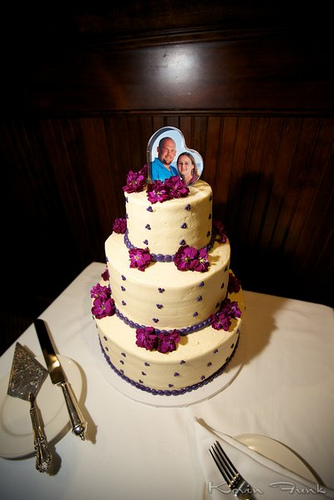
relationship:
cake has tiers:
[90, 125, 249, 400] [82, 183, 261, 398]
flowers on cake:
[122, 167, 196, 204] [90, 125, 249, 400]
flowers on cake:
[108, 220, 230, 271] [90, 125, 249, 400]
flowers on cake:
[90, 283, 245, 352] [90, 125, 249, 400]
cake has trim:
[90, 125, 249, 400] [120, 233, 176, 264]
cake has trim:
[90, 125, 249, 400] [112, 308, 224, 334]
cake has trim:
[90, 125, 249, 400] [104, 370, 237, 397]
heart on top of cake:
[144, 124, 210, 186] [90, 125, 249, 400]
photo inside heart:
[153, 137, 196, 181] [144, 124, 210, 186]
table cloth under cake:
[2, 256, 333, 497] [90, 125, 249, 400]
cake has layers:
[90, 125, 249, 400] [82, 183, 261, 398]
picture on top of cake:
[153, 137, 196, 181] [90, 125, 249, 400]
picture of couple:
[153, 137, 196, 181] [156, 138, 196, 174]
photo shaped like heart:
[153, 137, 196, 181] [144, 124, 210, 186]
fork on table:
[207, 441, 260, 498] [0, 242, 332, 496]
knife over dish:
[33, 315, 88, 448] [1, 343, 93, 476]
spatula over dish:
[4, 337, 59, 475] [1, 343, 93, 476]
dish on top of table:
[1, 343, 93, 476] [0, 242, 332, 496]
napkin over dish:
[195, 431, 330, 497] [234, 428, 322, 483]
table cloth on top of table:
[2, 256, 333, 497] [0, 242, 332, 496]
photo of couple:
[153, 137, 196, 181] [156, 138, 196, 174]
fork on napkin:
[207, 441, 260, 498] [195, 431, 330, 497]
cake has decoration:
[90, 125, 249, 400] [144, 124, 210, 186]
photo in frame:
[153, 137, 196, 181] [139, 127, 210, 184]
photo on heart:
[153, 137, 196, 181] [144, 124, 210, 186]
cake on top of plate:
[90, 125, 249, 400] [98, 354, 251, 411]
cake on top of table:
[90, 125, 249, 400] [0, 242, 332, 496]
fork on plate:
[207, 441, 260, 498] [234, 428, 322, 483]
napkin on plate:
[195, 431, 330, 497] [234, 428, 322, 483]